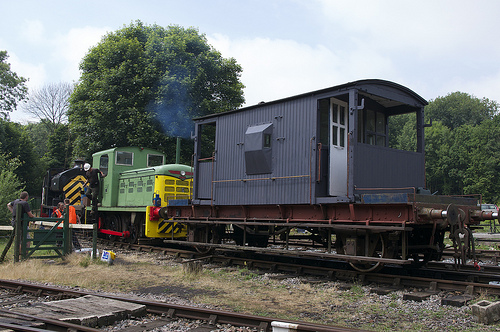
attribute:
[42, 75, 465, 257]
train — black, green, small, brown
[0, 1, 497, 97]
sky — blue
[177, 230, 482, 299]
tracks — red, black, brown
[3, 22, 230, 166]
trees — green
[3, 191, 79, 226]
men — white